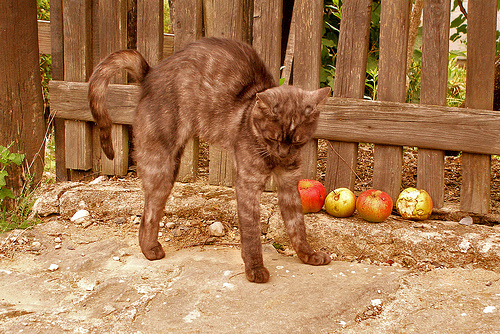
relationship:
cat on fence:
[87, 36, 332, 284] [43, 1, 498, 217]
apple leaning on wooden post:
[397, 187, 432, 218] [417, 2, 449, 209]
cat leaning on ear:
[87, 28, 332, 285] [312, 87, 329, 109]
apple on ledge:
[294, 173, 325, 217] [33, 168, 494, 266]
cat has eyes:
[87, 28, 332, 285] [266, 132, 306, 147]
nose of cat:
[277, 145, 290, 159] [87, 28, 332, 285]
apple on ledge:
[324, 182, 351, 215] [33, 168, 494, 266]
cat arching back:
[87, 28, 332, 285] [155, 22, 259, 109]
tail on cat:
[88, 80, 120, 160] [138, 40, 327, 162]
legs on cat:
[133, 131, 334, 283] [87, 28, 332, 285]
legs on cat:
[276, 160, 330, 278] [87, 28, 332, 285]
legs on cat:
[129, 131, 179, 265] [87, 28, 332, 285]